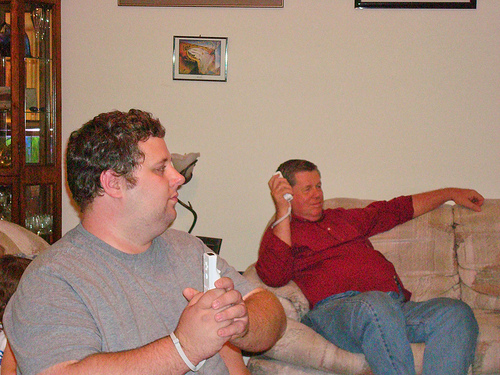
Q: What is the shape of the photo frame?
A: Rectangular.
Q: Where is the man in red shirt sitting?
A: On the sofa.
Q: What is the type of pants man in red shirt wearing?
A: Jeans.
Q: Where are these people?
A: In the living room.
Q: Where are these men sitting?
A: Couch.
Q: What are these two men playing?
A: Wii.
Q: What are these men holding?
A: Wii remotes.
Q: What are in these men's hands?
A: Wii controllers.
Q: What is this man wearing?
A: A red shirt and blue jeans.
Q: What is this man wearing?
A: Grey t-shirt.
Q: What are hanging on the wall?
A: Pictures.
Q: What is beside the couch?
A: Side table.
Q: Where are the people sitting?
A: In a living room.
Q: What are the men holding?
A: Game controllers.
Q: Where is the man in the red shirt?
A: On the couch.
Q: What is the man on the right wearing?
A: A red shirt and blue jeans.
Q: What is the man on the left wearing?
A: A gray shirt.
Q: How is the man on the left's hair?
A: Curly.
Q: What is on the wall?
A: Pictures.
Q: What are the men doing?
A: Playing a game.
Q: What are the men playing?
A: A video game.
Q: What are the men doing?
A: Playing wii.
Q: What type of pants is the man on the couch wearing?
A: Jeans.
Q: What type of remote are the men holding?
A: Wii.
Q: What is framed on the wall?
A: Picture.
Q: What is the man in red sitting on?
A: Couch.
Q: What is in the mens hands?
A: Controllers.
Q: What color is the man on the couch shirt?
A: Red.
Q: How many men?
A: 2.